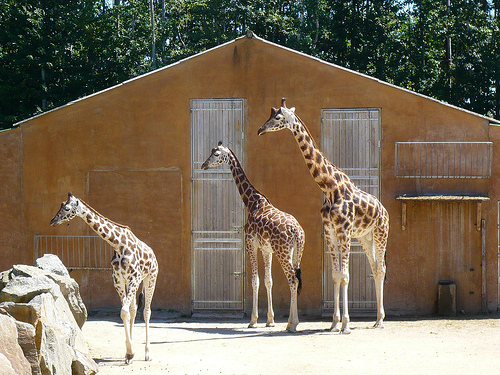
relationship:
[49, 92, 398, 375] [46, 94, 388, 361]
family of giraffes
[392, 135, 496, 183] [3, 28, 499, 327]
railing attached to building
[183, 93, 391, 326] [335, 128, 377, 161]
two doors will open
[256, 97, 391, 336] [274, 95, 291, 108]
giraffes has horn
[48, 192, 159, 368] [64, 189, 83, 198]
giraffe has horn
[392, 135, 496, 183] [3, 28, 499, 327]
railing fixed to building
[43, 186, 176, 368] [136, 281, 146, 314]
giraffe has tail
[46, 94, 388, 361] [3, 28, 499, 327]
giraffes are by building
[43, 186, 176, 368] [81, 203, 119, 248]
giraffe has long neck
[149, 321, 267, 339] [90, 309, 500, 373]
shadow on ground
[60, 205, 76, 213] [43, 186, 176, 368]
left eye of giraffe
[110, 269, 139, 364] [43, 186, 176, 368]
front legs of giraffe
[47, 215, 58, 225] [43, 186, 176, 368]
nose of giraffe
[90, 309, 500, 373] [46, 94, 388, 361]
ground below giraffes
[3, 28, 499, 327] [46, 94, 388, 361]
building behind giraffes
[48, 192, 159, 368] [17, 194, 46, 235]
giraffe looking left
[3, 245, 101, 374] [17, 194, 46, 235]
rocks are on left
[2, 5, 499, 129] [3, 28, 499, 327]
trees are above building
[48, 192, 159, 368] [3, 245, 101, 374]
giraffe standing by rocks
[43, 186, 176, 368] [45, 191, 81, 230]
giraffe has head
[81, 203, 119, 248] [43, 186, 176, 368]
long neck of giraffe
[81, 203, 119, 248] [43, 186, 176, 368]
long neck of a giraffe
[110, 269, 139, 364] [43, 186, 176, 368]
front legs of a giraffe